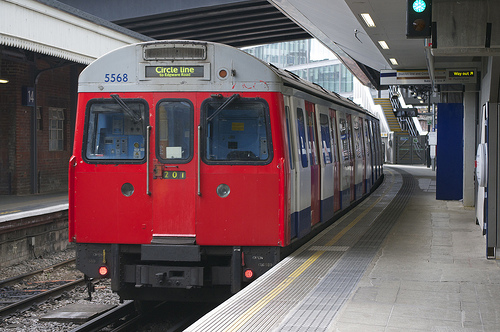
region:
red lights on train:
[236, 264, 261, 285]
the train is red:
[237, 202, 267, 238]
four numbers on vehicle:
[104, 66, 140, 99]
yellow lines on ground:
[267, 283, 295, 308]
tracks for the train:
[33, 268, 60, 311]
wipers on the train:
[199, 96, 255, 121]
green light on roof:
[406, 1, 435, 38]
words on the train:
[150, 64, 202, 81]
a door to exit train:
[156, 96, 192, 244]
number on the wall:
[24, 93, 56, 113]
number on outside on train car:
[93, 61, 137, 89]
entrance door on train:
[139, 86, 216, 258]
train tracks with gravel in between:
[0, 223, 340, 330]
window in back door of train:
[147, 89, 209, 186]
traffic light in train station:
[393, 0, 436, 40]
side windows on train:
[279, 78, 406, 192]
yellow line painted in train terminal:
[229, 106, 421, 299]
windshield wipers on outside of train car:
[191, 83, 258, 153]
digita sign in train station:
[436, 57, 486, 92]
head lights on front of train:
[201, 176, 250, 211]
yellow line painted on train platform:
[259, 270, 311, 312]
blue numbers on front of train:
[97, 67, 134, 84]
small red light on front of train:
[84, 259, 119, 284]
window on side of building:
[41, 101, 75, 152]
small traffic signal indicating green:
[403, 0, 433, 47]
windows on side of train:
[272, 97, 389, 229]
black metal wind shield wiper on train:
[105, 89, 145, 130]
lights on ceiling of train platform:
[359, 5, 400, 67]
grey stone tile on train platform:
[376, 284, 466, 329]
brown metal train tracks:
[8, 269, 73, 310]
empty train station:
[37, 15, 483, 297]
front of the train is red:
[61, 88, 303, 252]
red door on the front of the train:
[139, 85, 199, 242]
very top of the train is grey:
[79, 36, 275, 93]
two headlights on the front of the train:
[115, 180, 237, 202]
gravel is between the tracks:
[8, 256, 109, 324]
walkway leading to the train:
[358, 190, 479, 312]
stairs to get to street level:
[372, 87, 429, 169]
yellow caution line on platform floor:
[261, 262, 313, 310]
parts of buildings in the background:
[268, 33, 359, 102]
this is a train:
[57, 18, 374, 282]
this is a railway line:
[8, 265, 70, 321]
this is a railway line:
[37, 232, 101, 329]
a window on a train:
[83, 97, 158, 160]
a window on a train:
[147, 98, 213, 179]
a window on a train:
[201, 88, 297, 175]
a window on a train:
[291, 101, 316, 171]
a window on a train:
[321, 109, 333, 164]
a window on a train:
[334, 110, 354, 156]